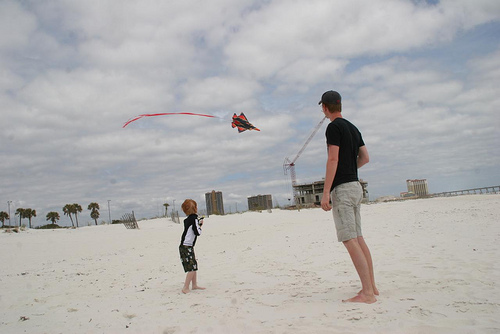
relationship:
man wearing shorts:
[318, 90, 380, 304] [330, 181, 365, 241]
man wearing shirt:
[318, 90, 380, 304] [326, 116, 365, 190]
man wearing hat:
[318, 90, 380, 304] [319, 90, 343, 107]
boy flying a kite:
[179, 199, 206, 294] [123, 111, 261, 133]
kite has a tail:
[123, 111, 261, 133] [123, 112, 226, 128]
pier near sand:
[383, 184, 500, 200] [1, 192, 499, 333]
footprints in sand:
[1, 192, 500, 332] [1, 192, 499, 333]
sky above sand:
[0, 1, 500, 227] [1, 192, 499, 333]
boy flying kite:
[179, 199, 206, 294] [123, 111, 261, 133]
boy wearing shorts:
[179, 199, 206, 294] [179, 244, 198, 272]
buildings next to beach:
[205, 179, 429, 216] [0, 191, 500, 333]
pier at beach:
[383, 184, 500, 200] [0, 191, 500, 333]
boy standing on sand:
[179, 199, 206, 294] [1, 192, 499, 333]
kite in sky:
[123, 111, 261, 133] [0, 1, 500, 227]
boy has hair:
[179, 199, 206, 294] [181, 198, 198, 216]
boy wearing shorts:
[179, 199, 206, 294] [330, 181, 365, 241]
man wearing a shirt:
[318, 90, 380, 304] [326, 116, 365, 190]